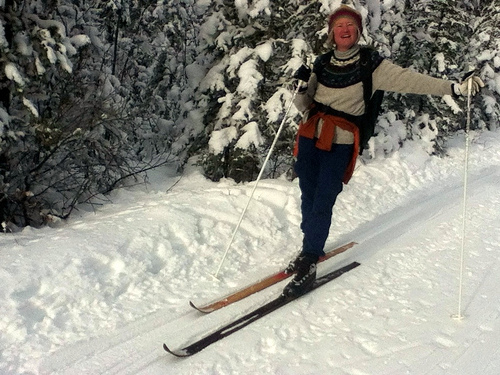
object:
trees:
[0, 0, 88, 230]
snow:
[202, 59, 264, 88]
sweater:
[289, 47, 456, 147]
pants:
[291, 130, 355, 259]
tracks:
[38, 262, 109, 320]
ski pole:
[448, 71, 476, 327]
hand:
[454, 69, 486, 99]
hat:
[326, 3, 365, 35]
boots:
[282, 260, 318, 298]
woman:
[274, 2, 489, 301]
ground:
[0, 133, 500, 375]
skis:
[188, 238, 361, 315]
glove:
[291, 61, 315, 83]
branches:
[3, 12, 98, 65]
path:
[0, 129, 499, 375]